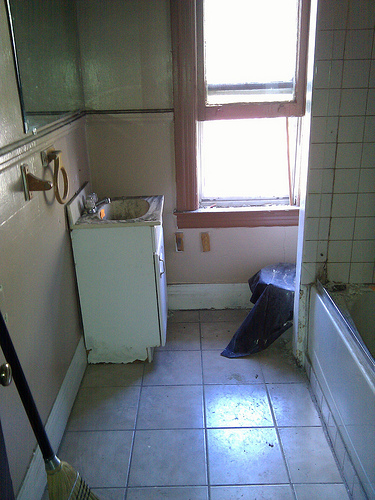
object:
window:
[171, 0, 310, 228]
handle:
[0, 356, 12, 392]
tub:
[303, 280, 374, 495]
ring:
[40, 152, 72, 204]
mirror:
[3, 0, 169, 138]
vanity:
[63, 192, 171, 364]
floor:
[39, 308, 355, 498]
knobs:
[79, 184, 98, 218]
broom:
[0, 315, 102, 499]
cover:
[219, 266, 298, 360]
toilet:
[0, 0, 375, 500]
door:
[148, 232, 169, 348]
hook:
[18, 163, 54, 201]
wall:
[0, 0, 375, 499]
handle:
[157, 254, 166, 279]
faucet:
[85, 189, 111, 214]